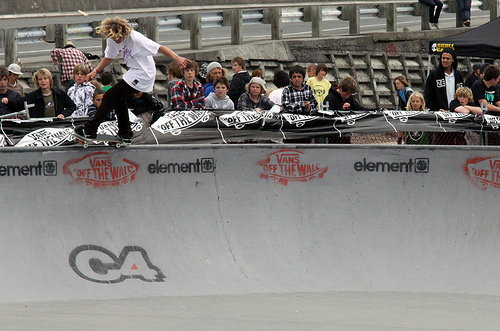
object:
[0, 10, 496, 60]
road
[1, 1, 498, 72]
background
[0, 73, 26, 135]
people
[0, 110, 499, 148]
banner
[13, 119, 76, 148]
decals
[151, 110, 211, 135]
decals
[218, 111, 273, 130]
decals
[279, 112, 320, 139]
decals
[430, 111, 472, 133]
decals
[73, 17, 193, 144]
boy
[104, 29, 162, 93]
shirt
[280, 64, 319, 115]
boy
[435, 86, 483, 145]
boy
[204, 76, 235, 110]
boy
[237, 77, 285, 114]
boy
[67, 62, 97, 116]
boy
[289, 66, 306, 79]
black haired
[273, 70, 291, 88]
black haired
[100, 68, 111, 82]
black haired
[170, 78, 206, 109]
plaid shirt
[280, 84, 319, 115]
plaid shirt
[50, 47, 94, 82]
plaid shirt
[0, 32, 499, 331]
skatepark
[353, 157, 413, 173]
word element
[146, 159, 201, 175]
word element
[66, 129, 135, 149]
skateboard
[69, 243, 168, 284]
c4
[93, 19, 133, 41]
hair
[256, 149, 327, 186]
vans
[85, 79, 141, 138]
legs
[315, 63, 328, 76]
hair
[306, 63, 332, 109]
boy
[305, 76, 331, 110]
shirt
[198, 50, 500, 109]
barrier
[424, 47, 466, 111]
adult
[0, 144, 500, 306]
ramp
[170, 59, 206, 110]
boy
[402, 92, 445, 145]
girl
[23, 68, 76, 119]
man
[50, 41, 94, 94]
man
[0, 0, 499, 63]
rail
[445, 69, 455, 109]
shirt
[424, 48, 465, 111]
jacket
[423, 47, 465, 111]
coat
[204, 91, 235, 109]
sweatshirt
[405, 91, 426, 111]
hair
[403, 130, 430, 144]
shirt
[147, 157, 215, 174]
name